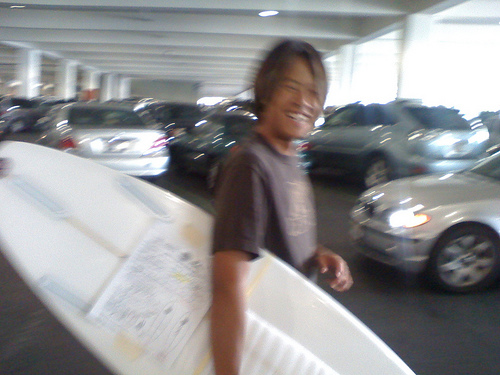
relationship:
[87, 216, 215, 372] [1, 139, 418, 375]
paper attached to surfboard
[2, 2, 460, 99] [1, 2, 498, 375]
roof covering garage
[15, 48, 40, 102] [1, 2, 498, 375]
column standing in garage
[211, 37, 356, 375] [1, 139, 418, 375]
surfer carrying surfboard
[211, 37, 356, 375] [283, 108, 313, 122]
surfer has a smile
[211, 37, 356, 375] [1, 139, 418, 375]
surfer walking with a surfboard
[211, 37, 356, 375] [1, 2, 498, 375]
surfer in a garage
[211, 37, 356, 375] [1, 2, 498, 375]
surfer walking in a garage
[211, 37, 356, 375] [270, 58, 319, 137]
surfer has a face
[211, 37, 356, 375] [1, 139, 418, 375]
surfer carrying a surfboard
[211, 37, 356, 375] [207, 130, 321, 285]
surfer wearing a shirt